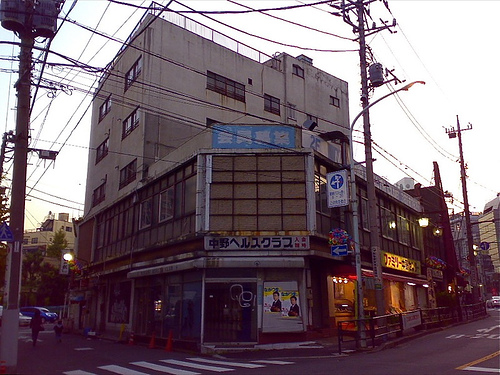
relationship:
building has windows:
[66, 12, 354, 347] [186, 64, 319, 114]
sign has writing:
[205, 125, 305, 151] [223, 133, 289, 144]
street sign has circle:
[323, 171, 352, 212] [327, 175, 347, 191]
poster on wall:
[264, 287, 305, 319] [266, 267, 314, 358]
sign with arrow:
[328, 242, 353, 262] [334, 249, 346, 255]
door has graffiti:
[204, 284, 264, 348] [227, 283, 256, 312]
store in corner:
[320, 277, 386, 331] [326, 271, 330, 331]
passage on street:
[342, 311, 451, 327] [382, 318, 494, 354]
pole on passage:
[349, 211, 372, 349] [319, 299, 490, 354]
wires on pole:
[375, 85, 462, 165] [349, 211, 372, 349]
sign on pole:
[328, 242, 353, 262] [349, 211, 372, 349]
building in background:
[66, 12, 354, 347] [28, 37, 480, 209]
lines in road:
[135, 351, 227, 374] [33, 342, 128, 368]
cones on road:
[122, 330, 187, 353] [33, 342, 128, 368]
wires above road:
[34, 23, 96, 182] [33, 342, 128, 368]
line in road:
[460, 353, 500, 364] [33, 342, 128, 368]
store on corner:
[320, 277, 386, 331] [326, 271, 330, 331]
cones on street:
[122, 330, 187, 353] [382, 318, 494, 354]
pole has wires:
[348, 22, 395, 321] [375, 85, 462, 165]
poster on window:
[264, 287, 305, 319] [261, 272, 308, 334]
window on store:
[171, 183, 188, 239] [320, 277, 386, 331]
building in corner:
[66, 12, 354, 347] [326, 271, 330, 331]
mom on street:
[29, 308, 45, 350] [382, 318, 494, 354]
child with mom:
[53, 318, 67, 342] [29, 309, 42, 352]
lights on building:
[418, 211, 443, 233] [66, 12, 354, 347]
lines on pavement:
[135, 351, 227, 374] [59, 340, 203, 374]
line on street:
[460, 353, 500, 364] [382, 318, 494, 354]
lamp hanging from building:
[415, 201, 434, 230] [356, 183, 469, 321]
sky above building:
[354, 27, 499, 118] [66, 12, 354, 347]